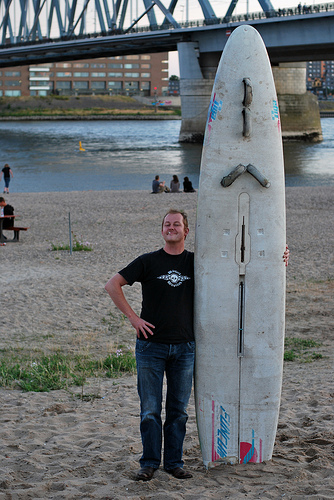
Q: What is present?
A: Water.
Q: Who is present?
A: A man.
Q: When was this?
A: Daytime.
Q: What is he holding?
A: A surfboard.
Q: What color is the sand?
A: Brown.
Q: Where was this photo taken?
A: Sea front.